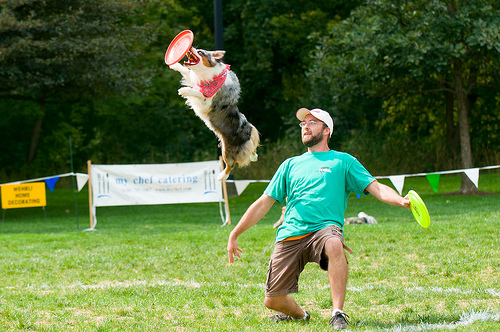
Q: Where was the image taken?
A: It was taken at the field.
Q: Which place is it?
A: It is a field.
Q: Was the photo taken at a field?
A: Yes, it was taken in a field.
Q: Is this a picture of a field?
A: Yes, it is showing a field.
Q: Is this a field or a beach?
A: It is a field.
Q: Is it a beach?
A: No, it is a field.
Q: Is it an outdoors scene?
A: Yes, it is outdoors.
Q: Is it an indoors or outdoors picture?
A: It is outdoors.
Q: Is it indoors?
A: No, it is outdoors.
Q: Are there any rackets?
A: No, there are no rackets.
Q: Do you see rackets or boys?
A: No, there are no rackets or boys.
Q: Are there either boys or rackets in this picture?
A: No, there are no rackets or boys.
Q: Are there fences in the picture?
A: No, there are no fences.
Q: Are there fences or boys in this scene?
A: No, there are no fences or boys.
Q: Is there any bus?
A: No, there are no buses.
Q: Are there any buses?
A: No, there are no buses.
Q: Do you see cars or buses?
A: No, there are no buses or cars.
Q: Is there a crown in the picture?
A: No, there are no crowns.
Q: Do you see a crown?
A: No, there are no crowns.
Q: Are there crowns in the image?
A: No, there are no crowns.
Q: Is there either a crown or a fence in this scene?
A: No, there are no crowns or fences.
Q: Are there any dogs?
A: Yes, there is a dog.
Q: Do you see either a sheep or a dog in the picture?
A: Yes, there is a dog.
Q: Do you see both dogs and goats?
A: No, there is a dog but no goats.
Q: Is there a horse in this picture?
A: No, there are no horses.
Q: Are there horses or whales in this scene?
A: No, there are no horses or whales.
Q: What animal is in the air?
A: The animal is a dog.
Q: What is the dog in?
A: The dog is in the air.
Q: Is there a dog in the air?
A: Yes, there is a dog in the air.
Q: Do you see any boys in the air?
A: No, there is a dog in the air.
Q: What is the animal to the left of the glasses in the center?
A: The animal is a dog.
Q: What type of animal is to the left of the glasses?
A: The animal is a dog.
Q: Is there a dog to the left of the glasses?
A: Yes, there is a dog to the left of the glasses.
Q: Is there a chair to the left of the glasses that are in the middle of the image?
A: No, there is a dog to the left of the glasses.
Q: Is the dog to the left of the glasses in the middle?
A: Yes, the dog is to the left of the glasses.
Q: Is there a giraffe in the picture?
A: No, there are no giraffes.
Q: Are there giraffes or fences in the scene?
A: No, there are no giraffes or fences.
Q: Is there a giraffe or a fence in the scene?
A: No, there are no giraffes or fences.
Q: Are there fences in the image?
A: No, there are no fences.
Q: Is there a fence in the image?
A: No, there are no fences.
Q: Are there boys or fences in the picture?
A: No, there are no fences or boys.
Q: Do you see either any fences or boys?
A: No, there are no fences or boys.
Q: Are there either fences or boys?
A: No, there are no fences or boys.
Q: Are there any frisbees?
A: Yes, there is a frisbee.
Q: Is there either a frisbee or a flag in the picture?
A: Yes, there is a frisbee.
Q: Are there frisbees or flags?
A: Yes, there is a frisbee.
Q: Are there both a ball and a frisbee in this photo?
A: No, there is a frisbee but no balls.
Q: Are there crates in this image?
A: No, there are no crates.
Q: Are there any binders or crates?
A: No, there are no crates or binders.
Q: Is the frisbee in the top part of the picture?
A: Yes, the frisbee is in the top of the image.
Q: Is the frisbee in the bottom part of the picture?
A: No, the frisbee is in the top of the image.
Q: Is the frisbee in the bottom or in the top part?
A: The frisbee is in the top of the image.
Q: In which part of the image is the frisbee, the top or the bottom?
A: The frisbee is in the top of the image.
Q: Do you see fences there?
A: No, there are no fences.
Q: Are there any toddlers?
A: No, there are no toddlers.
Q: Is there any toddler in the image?
A: No, there are no toddlers.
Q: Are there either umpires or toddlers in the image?
A: No, there are no toddlers or umpires.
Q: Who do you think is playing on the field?
A: The man is playing on the field.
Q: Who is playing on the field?
A: The man is playing on the field.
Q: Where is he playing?
A: The man is playing on the field.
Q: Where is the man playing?
A: The man is playing on the field.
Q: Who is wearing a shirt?
A: The man is wearing a shirt.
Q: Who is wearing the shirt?
A: The man is wearing a shirt.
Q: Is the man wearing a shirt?
A: Yes, the man is wearing a shirt.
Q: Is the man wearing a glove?
A: No, the man is wearing a shirt.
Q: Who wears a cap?
A: The man wears a cap.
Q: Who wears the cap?
A: The man wears a cap.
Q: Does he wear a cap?
A: Yes, the man wears a cap.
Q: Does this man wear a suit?
A: No, the man wears a cap.